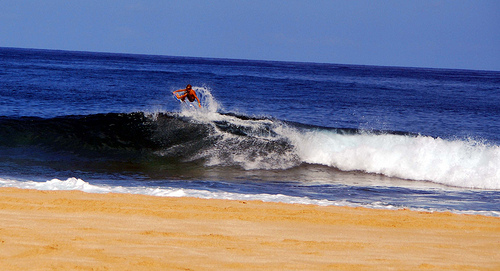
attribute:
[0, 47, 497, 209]
water — blue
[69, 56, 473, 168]
water — blue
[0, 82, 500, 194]
wave — large